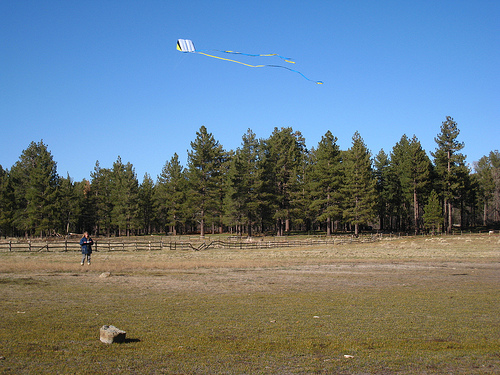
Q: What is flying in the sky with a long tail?
A: Kite.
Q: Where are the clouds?
A: There are none.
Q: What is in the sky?
A: Kite.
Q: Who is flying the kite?
A: Girl in field.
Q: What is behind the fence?
A: Trees.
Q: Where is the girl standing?
A: On the grass.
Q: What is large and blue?
A: The sky.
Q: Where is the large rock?
A: In the grass.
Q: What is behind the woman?
A: Fence.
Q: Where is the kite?
A: In the sky.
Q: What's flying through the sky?
A: Kite.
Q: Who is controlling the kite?
A: A man.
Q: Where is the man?
A: In a field.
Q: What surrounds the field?
A: Trees.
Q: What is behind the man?
A: Fence.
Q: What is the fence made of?
A: Wood.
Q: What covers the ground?
A: Grass.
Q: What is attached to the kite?
A: Ribbons.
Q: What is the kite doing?
A: Flying.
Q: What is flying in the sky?
A: A kite.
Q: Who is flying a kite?
A: A woman.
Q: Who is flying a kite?
A: A woman.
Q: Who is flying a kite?
A: A woman.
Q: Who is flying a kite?
A: A woman.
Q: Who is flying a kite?
A: A woman.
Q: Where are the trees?
A: In the forest.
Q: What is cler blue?
A: Sky.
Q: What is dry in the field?
A: Grass.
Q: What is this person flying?
A: Kite.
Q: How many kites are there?
A: 1.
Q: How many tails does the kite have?
A: 2.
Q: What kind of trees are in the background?
A: Pine.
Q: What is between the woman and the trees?
A: Fence.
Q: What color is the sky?
A: Blue.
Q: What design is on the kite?
A: Stripes.